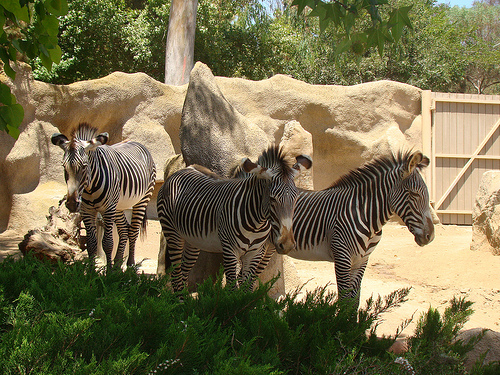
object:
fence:
[8, 71, 422, 223]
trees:
[209, 7, 496, 77]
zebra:
[51, 123, 157, 273]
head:
[51, 126, 110, 214]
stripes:
[180, 187, 262, 237]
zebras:
[227, 162, 434, 320]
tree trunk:
[164, 1, 203, 87]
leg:
[334, 261, 354, 308]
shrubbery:
[405, 294, 487, 374]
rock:
[1, 57, 53, 257]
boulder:
[0, 57, 440, 260]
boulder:
[468, 168, 498, 254]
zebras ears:
[400, 150, 424, 182]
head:
[384, 151, 434, 246]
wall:
[3, 55, 424, 275]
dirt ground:
[417, 270, 477, 297]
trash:
[366, 339, 443, 360]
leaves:
[277, 4, 448, 63]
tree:
[165, 0, 198, 85]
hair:
[325, 151, 420, 190]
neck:
[355, 169, 395, 240]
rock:
[178, 60, 270, 178]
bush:
[5, 252, 497, 372]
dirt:
[394, 267, 442, 291]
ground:
[385, 232, 498, 324]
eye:
[270, 196, 277, 202]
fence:
[421, 90, 498, 225]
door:
[428, 91, 498, 226]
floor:
[477, 271, 499, 327]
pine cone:
[151, 361, 198, 373]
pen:
[0, 88, 499, 374]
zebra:
[156, 146, 313, 304]